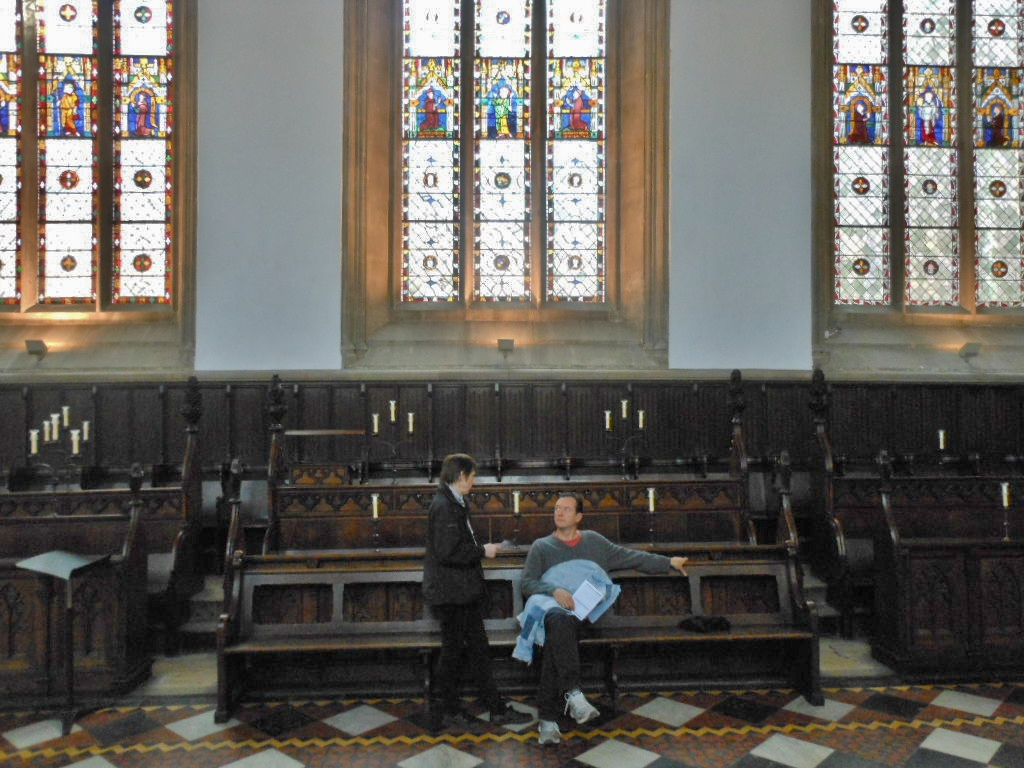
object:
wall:
[0, 0, 1024, 378]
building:
[0, 0, 1013, 764]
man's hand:
[551, 587, 575, 611]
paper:
[570, 574, 622, 624]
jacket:
[512, 560, 622, 668]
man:
[521, 493, 690, 745]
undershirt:
[556, 529, 583, 547]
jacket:
[422, 486, 490, 607]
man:
[422, 453, 534, 732]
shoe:
[564, 689, 600, 724]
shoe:
[539, 718, 566, 744]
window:
[342, 0, 670, 370]